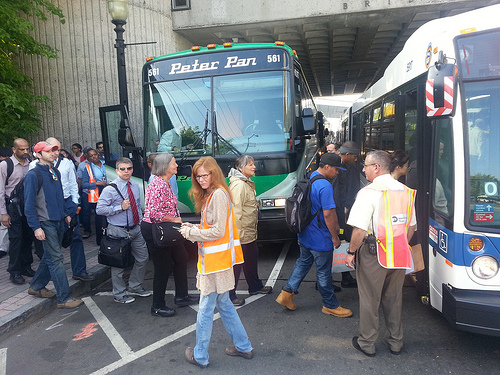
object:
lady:
[174, 153, 259, 364]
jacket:
[178, 185, 246, 276]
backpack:
[285, 174, 329, 234]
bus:
[137, 38, 326, 248]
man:
[0, 137, 41, 285]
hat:
[321, 152, 348, 171]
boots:
[322, 300, 353, 318]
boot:
[278, 288, 306, 311]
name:
[168, 56, 258, 75]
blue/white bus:
[336, 2, 500, 337]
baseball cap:
[33, 142, 59, 153]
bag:
[151, 215, 190, 248]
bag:
[60, 220, 79, 250]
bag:
[5, 168, 43, 223]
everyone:
[21, 141, 85, 313]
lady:
[147, 150, 199, 318]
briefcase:
[98, 184, 131, 269]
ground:
[332, 330, 500, 375]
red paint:
[69, 319, 101, 344]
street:
[1, 232, 498, 372]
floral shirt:
[139, 173, 181, 228]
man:
[100, 157, 150, 303]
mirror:
[296, 107, 316, 135]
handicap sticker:
[438, 229, 447, 254]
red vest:
[362, 180, 418, 277]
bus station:
[0, 1, 498, 372]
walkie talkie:
[367, 232, 377, 255]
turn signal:
[468, 236, 483, 252]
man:
[343, 150, 416, 357]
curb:
[0, 274, 104, 341]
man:
[277, 154, 355, 318]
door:
[95, 104, 146, 179]